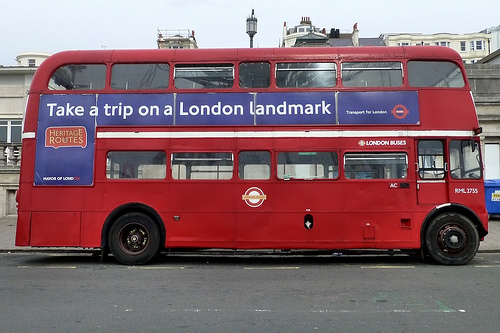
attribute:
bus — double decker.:
[18, 29, 491, 288]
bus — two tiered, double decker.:
[36, 45, 486, 271]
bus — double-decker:
[23, 43, 490, 298]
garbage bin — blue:
[484, 176, 497, 217]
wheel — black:
[419, 206, 480, 264]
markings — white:
[106, 295, 484, 316]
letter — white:
[44, 95, 58, 116]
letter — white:
[55, 99, 69, 119]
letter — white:
[64, 94, 76, 121]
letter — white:
[86, 104, 107, 120]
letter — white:
[88, 99, 104, 122]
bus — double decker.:
[4, 35, 494, 264]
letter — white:
[101, 103, 117, 121]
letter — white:
[104, 101, 124, 117]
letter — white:
[121, 101, 142, 119]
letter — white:
[119, 103, 135, 128]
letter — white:
[133, 95, 147, 116]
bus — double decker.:
[14, 38, 469, 280]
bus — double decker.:
[19, 21, 479, 271]